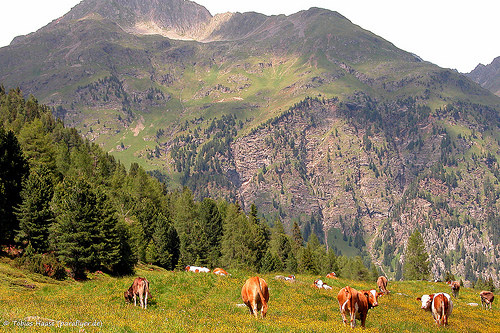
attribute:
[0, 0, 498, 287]
mountain — rocky side 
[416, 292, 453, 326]
cow — white , brown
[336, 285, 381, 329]
cow — brown 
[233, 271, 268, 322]
cow — brown 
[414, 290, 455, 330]
cow — brown 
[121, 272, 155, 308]
cow — brown 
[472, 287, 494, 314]
cow — brown 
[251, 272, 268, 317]
tail — brown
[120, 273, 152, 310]
cow — grazing  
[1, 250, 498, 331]
grass field — green 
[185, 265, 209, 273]
cow —  laying down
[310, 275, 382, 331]
cow — brown, white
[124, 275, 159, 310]
cow — brown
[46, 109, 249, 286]
trees — side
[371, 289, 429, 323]
flowers — yellow wildflowers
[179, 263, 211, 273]
cow — white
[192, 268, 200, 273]
spots — brown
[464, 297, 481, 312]
rock — large white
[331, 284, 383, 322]
white cow — white , little brown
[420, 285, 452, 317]
brown cow — little brown, white 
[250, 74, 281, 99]
grass — green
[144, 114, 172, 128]
grass — green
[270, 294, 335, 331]
grass — green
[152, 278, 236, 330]
grass — green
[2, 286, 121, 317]
grass — green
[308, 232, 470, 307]
cows — two brown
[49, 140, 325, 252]
trees — side 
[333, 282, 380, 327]
cow — brown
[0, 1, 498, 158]
mountains — rocky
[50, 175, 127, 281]
tree — tall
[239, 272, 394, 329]
cows — brown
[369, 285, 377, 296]
spot — white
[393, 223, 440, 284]
tree — tall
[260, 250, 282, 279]
tree — tall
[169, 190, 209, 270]
tree — tall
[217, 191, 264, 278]
tree — tall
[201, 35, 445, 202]
mountain — side 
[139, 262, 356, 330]
grass —  green 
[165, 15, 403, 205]
mountain — side